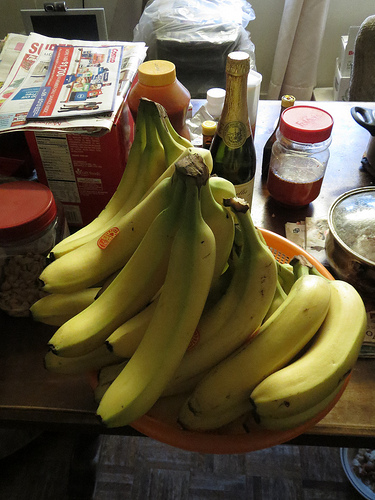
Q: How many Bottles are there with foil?
A: One.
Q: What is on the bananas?
A: Stickers.